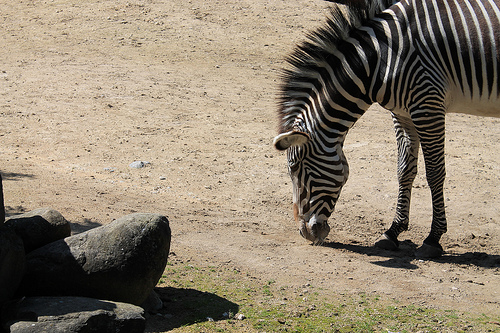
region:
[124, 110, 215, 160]
brown dirt on ground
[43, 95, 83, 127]
brown dirt on ground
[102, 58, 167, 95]
brown dirt on ground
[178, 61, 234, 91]
brown dirt on ground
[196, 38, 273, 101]
brown dirt on ground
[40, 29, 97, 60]
brown dirt on ground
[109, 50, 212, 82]
brown dirt on ground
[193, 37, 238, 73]
brown dirt on ground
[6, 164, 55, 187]
brown dirt on ground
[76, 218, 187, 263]
large gray rock on ground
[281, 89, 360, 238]
HEAD OF A ZEBRA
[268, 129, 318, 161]
EAR OF THE ZEBRA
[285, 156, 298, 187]
EYE OF THE ZEBRA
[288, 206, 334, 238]
MOUTH OF THE ZEBRA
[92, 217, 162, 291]
THIS IS A STONE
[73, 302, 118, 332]
THIS IS A STONE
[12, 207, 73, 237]
THIS IS A STONE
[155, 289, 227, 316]
THAT IS A SHADOW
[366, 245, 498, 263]
THAT IS A SHADOW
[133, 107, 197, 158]
THE GROUND IS DRY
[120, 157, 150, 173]
Rock on bare ground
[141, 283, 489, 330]
Small patch of green grass on ground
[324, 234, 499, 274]
Shadow of zebra on ground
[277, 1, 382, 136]
Black and white mane of zebra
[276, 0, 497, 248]
Zebra grazing for food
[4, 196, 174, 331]
Large rocks on ground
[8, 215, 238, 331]
Shadows of rocks on ground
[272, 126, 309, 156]
Ears on zebra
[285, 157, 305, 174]
Black eye of zebra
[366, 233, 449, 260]
Front hooves of zebra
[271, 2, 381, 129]
mane of giraffe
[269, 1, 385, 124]
white and black mane of giraffe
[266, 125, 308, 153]
an ear of zebra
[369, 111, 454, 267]
front legs of zebra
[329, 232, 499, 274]
shadow on the ground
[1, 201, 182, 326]
rocks on the ground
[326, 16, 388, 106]
wide stripes on neck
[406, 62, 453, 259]
thin stripes on leg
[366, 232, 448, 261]
hooves of front legs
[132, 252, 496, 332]
a patch of grass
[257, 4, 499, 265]
zebra standing in the dirt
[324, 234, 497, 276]
shadow from the zebra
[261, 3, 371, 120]
long hair sticking up on the neck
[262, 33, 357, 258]
head is bent down towards the ground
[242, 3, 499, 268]
black and white zebra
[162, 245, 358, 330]
small patch of grass in the dirt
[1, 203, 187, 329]
several boulders on the ground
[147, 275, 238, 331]
shadow from the boulder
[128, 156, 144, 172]
small rock on the dirt